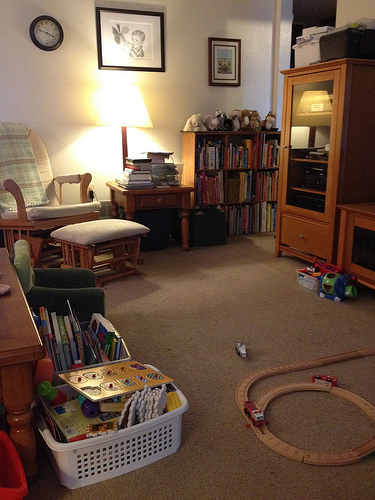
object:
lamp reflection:
[294, 90, 332, 150]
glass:
[283, 81, 333, 215]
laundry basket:
[31, 359, 192, 493]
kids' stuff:
[36, 361, 183, 445]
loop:
[255, 380, 375, 468]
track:
[234, 346, 375, 468]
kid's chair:
[13, 239, 106, 322]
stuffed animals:
[182, 113, 209, 133]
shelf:
[181, 131, 283, 243]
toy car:
[312, 256, 343, 279]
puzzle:
[57, 360, 174, 403]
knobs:
[82, 371, 103, 381]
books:
[30, 298, 122, 373]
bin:
[51, 312, 132, 386]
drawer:
[140, 194, 176, 210]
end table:
[106, 179, 195, 253]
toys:
[312, 373, 339, 386]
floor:
[150, 253, 290, 340]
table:
[1, 245, 45, 477]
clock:
[29, 14, 65, 53]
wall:
[1, 54, 99, 129]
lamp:
[85, 78, 156, 173]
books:
[195, 135, 226, 170]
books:
[117, 151, 179, 190]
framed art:
[95, 6, 166, 73]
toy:
[235, 341, 248, 359]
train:
[243, 398, 264, 428]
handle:
[282, 144, 292, 149]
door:
[280, 69, 341, 227]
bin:
[0, 430, 32, 500]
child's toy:
[317, 271, 359, 304]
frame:
[94, 3, 105, 71]